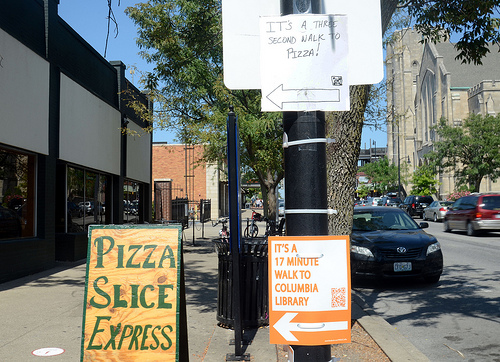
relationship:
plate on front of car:
[390, 257, 418, 276] [343, 194, 446, 284]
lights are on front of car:
[350, 236, 442, 261] [343, 194, 446, 284]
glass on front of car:
[351, 209, 418, 232] [343, 194, 446, 284]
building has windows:
[5, 2, 152, 280] [3, 147, 150, 231]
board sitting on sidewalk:
[82, 220, 187, 362] [0, 200, 383, 361]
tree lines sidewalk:
[120, 0, 498, 152] [0, 200, 383, 361]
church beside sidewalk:
[381, 25, 498, 217] [0, 200, 383, 361]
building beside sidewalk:
[5, 2, 152, 280] [0, 200, 383, 361]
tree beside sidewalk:
[120, 0, 498, 152] [0, 200, 383, 361]